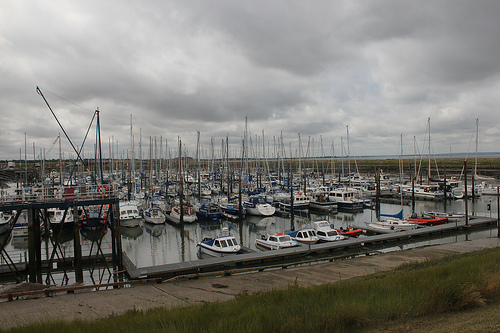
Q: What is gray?
A: The sky.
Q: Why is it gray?
A: It's going to rain.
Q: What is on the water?
A: Boats.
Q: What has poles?
A: Boats.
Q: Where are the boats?
A: On the water.